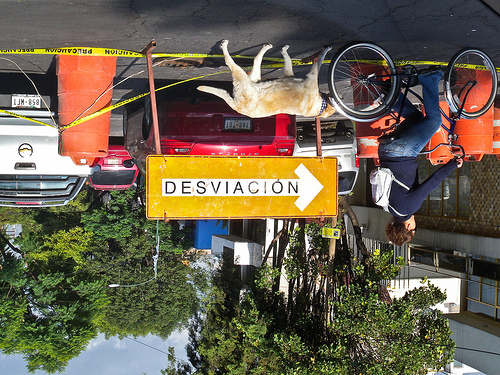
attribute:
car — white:
[0, 92, 102, 207]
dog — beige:
[197, 37, 334, 122]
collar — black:
[316, 94, 327, 114]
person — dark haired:
[367, 65, 462, 247]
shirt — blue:
[378, 155, 460, 220]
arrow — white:
[139, 143, 350, 233]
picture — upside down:
[2, 6, 498, 373]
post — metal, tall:
[90, 208, 179, 311]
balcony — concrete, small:
[209, 232, 260, 267]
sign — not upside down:
[152, 154, 341, 229]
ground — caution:
[40, 14, 469, 55]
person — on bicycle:
[383, 92, 440, 246]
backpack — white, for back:
[352, 151, 399, 206]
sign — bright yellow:
[138, 155, 338, 223]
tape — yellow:
[398, 30, 462, 88]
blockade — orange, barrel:
[54, 50, 116, 166]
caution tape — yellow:
[0, 42, 498, 130]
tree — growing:
[222, 223, 469, 372]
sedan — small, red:
[158, 95, 298, 155]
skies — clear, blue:
[93, 346, 146, 368]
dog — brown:
[196, 30, 346, 117]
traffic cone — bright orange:
[56, 53, 120, 164]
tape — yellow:
[15, 36, 485, 83]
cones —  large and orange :
[50, 77, 108, 168]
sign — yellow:
[136, 168, 336, 204]